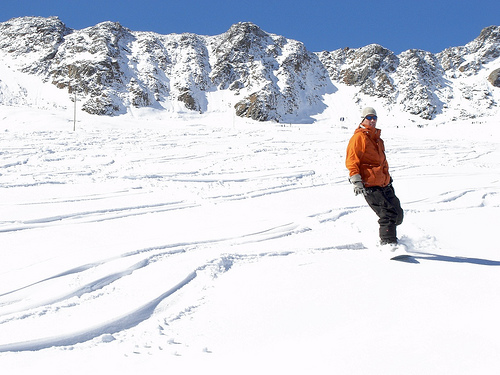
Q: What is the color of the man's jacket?
A: Orange.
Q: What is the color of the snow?
A: White.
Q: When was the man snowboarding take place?
A: Daytime.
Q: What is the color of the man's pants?
A: Black.